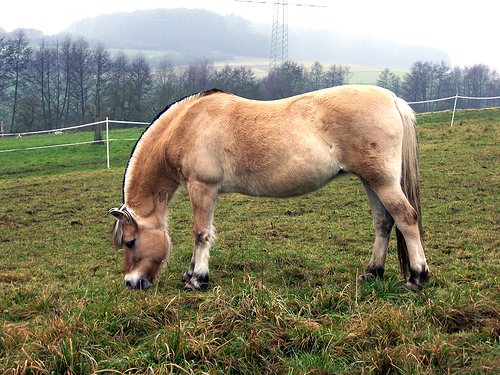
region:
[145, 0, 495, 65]
light in daytime sky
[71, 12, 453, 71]
haze on tree lined horizon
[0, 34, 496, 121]
line of leafless trees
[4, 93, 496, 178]
white lines on posts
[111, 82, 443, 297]
side of grazing horse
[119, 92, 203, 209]
trimed mane on neck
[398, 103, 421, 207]
tail on back of horse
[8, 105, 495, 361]
green grass of pasture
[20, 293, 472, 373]
mix of brown and green grass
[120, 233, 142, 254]
eye on horse face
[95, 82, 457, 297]
brown and white pony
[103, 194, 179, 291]
brown and white pony face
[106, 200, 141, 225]
pony ears sticking up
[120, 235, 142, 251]
large black pony eye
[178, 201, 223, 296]
two soft pony legs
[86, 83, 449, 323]
pony lending down to eat grass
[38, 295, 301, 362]
brown and green large grass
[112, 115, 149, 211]
black line of pony hair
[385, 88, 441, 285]
brown and black long pony tail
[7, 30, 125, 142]
tall trees without leaves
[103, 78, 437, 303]
A large animal grazing in a pasture.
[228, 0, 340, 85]
A tall metal object.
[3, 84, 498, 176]
A thin white fence.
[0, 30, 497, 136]
A long line of trees.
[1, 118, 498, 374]
A pasture full of grass.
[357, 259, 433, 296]
Two black hooves.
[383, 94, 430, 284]
A long animal tail.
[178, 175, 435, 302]
Four legs on a strong animal.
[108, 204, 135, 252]
A tuft of hair on an animal's head.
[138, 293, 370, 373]
Wisps of multi-colored vegetation.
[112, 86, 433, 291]
Donkey is eating grass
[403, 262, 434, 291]
Donkey's hoof is black and white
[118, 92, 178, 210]
The donkey's fur is brown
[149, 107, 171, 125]
It has a black stripe on its mane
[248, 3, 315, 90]
There is a cellphone tower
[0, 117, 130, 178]
There is a fence keeping the animal in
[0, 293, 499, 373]
Grass is green with brown patches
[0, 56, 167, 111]
dark trees line the background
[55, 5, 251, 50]
There is a gray cloud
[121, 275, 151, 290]
Donkey has black and white face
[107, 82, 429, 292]
horse grazing in the field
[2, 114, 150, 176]
fence to keep horse in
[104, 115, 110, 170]
post to hold up fence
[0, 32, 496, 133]
trees on the other side of the fence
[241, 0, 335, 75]
electrical tower behind the trees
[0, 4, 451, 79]
hills in the background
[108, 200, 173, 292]
brown and white horses head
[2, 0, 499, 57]
fog in the distance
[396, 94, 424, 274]
tail of the horse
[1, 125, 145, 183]
grass is a brighter green on this side of the fence